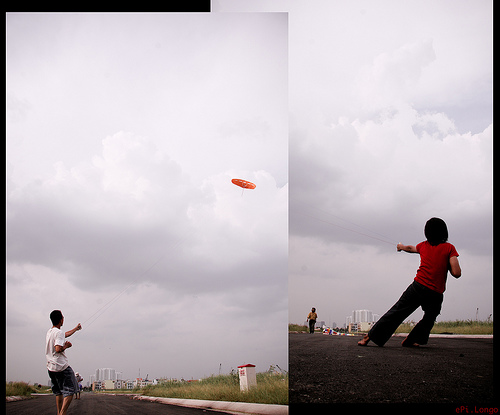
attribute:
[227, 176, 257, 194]
kite — orange, object, flying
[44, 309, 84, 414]
man — barefoot, flying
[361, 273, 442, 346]
pants — black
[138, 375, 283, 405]
grass — green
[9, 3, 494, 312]
sky — cloudy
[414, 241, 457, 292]
shirt — red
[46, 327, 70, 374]
shirt — white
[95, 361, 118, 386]
building — distant, tall, white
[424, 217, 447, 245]
hair — long, black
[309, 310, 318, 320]
shirt — yellow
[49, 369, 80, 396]
jeans — grey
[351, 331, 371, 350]
feet — bare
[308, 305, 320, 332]
man — walking